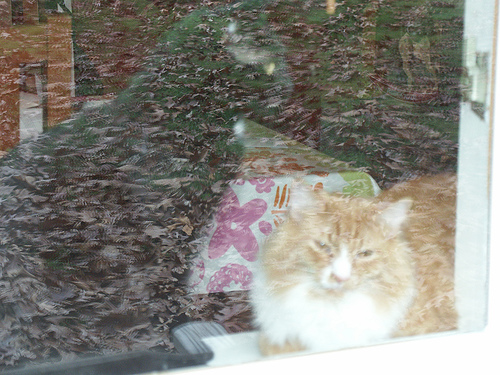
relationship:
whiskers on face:
[284, 264, 399, 302] [297, 194, 391, 294]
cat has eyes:
[247, 172, 471, 358] [308, 234, 383, 273]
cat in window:
[247, 172, 471, 358] [2, 1, 485, 371]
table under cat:
[203, 328, 265, 365] [238, 170, 430, 360]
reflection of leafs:
[25, 154, 152, 333] [58, 134, 200, 266]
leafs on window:
[58, 134, 200, 266] [43, 33, 474, 348]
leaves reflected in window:
[31, 7, 387, 115] [2, 1, 485, 371]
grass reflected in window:
[55, 120, 165, 264] [2, 1, 485, 371]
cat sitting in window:
[238, 170, 430, 360] [25, 29, 444, 371]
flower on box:
[206, 186, 268, 264] [148, 108, 383, 290]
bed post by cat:
[42, 12, 75, 128] [247, 172, 471, 358]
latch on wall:
[462, 56, 487, 118] [436, 15, 465, 361]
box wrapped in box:
[183, 112, 385, 299] [183, 112, 385, 299]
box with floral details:
[183, 112, 385, 299] [204, 180, 267, 262]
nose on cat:
[329, 269, 350, 283] [247, 172, 471, 358]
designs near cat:
[205, 184, 275, 305] [17, 4, 323, 361]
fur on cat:
[270, 287, 340, 344] [258, 185, 427, 325]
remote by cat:
[174, 312, 226, 346] [237, 171, 452, 346]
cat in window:
[0, 17, 317, 347] [206, 21, 325, 323]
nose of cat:
[329, 272, 350, 283] [247, 172, 471, 358]